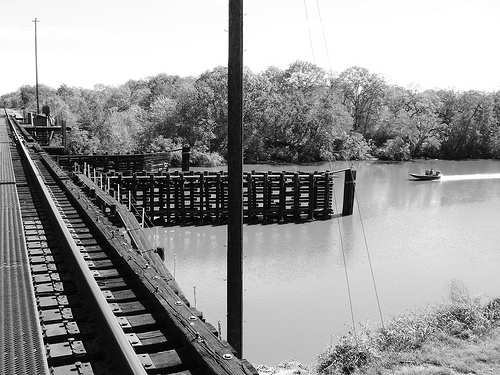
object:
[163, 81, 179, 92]
leaf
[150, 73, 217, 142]
plant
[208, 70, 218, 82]
leaf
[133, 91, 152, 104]
leaf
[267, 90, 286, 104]
leaf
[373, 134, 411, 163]
plant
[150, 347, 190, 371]
board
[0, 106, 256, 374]
bridge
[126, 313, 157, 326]
board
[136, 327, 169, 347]
board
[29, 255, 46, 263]
board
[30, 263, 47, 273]
board